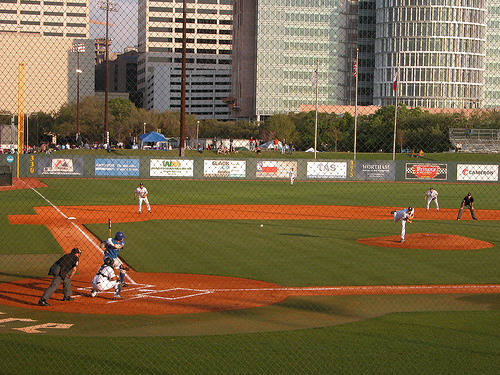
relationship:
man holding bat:
[100, 233, 128, 290] [86, 212, 119, 232]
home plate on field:
[140, 285, 155, 292] [5, 181, 497, 372]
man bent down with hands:
[454, 187, 484, 224] [456, 202, 477, 209]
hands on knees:
[456, 202, 477, 209] [457, 207, 481, 214]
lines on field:
[129, 274, 347, 301] [0, 14, 467, 373]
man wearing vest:
[33, 243, 83, 306] [46, 253, 79, 280]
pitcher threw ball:
[385, 195, 420, 245] [253, 219, 268, 231]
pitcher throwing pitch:
[385, 195, 420, 245] [257, 220, 267, 230]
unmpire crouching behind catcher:
[39, 246, 79, 303] [91, 257, 118, 297]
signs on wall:
[34, 157, 497, 184] [18, 155, 498, 181]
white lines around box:
[73, 279, 213, 305] [71, 274, 153, 293]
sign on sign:
[35, 154, 85, 177] [35, 154, 85, 177]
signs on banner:
[34, 157, 497, 184] [148, 158, 195, 177]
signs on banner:
[34, 157, 497, 184] [146, 161, 206, 184]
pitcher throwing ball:
[385, 195, 420, 245] [252, 210, 274, 232]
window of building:
[282, 25, 288, 37] [236, 0, 356, 117]